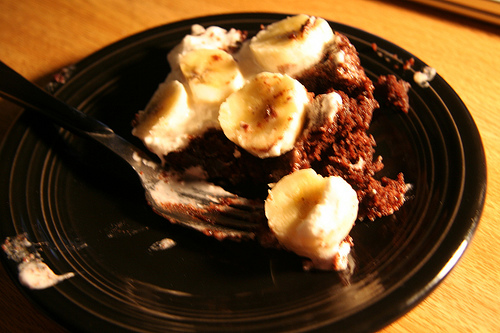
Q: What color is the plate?
A: Black.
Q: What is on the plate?
A: Banana cake.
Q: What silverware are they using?
A: Fork.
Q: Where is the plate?
A: Table.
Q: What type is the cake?
A: Chocolate.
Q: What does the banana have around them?
A: Frosting.